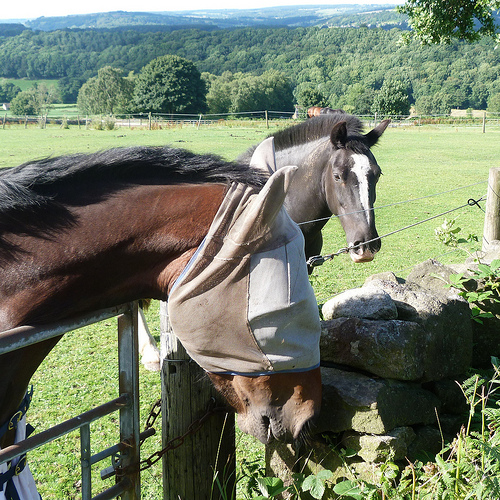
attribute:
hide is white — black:
[348, 149, 376, 228]